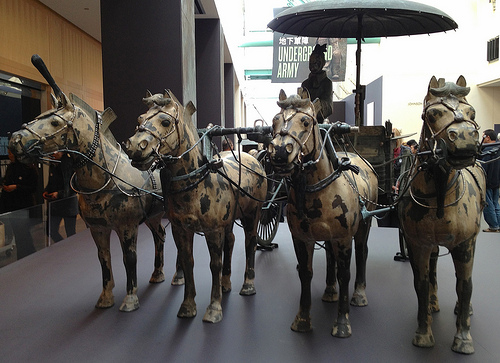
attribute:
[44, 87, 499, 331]
horses — statues, wooden, four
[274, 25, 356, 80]
sign — underground army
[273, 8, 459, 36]
umbrella — dark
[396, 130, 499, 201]
people — crowd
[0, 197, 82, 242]
shield — clear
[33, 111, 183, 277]
horse — wooden, on display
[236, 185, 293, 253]
wheel — black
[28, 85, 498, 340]
statues — horse, in row, horses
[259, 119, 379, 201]
chariot — hitched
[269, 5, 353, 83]
banner — large, hanging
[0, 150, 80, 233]
pedestrians — walking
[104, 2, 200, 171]
column — large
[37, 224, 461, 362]
ground — grey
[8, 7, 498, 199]
building — brown